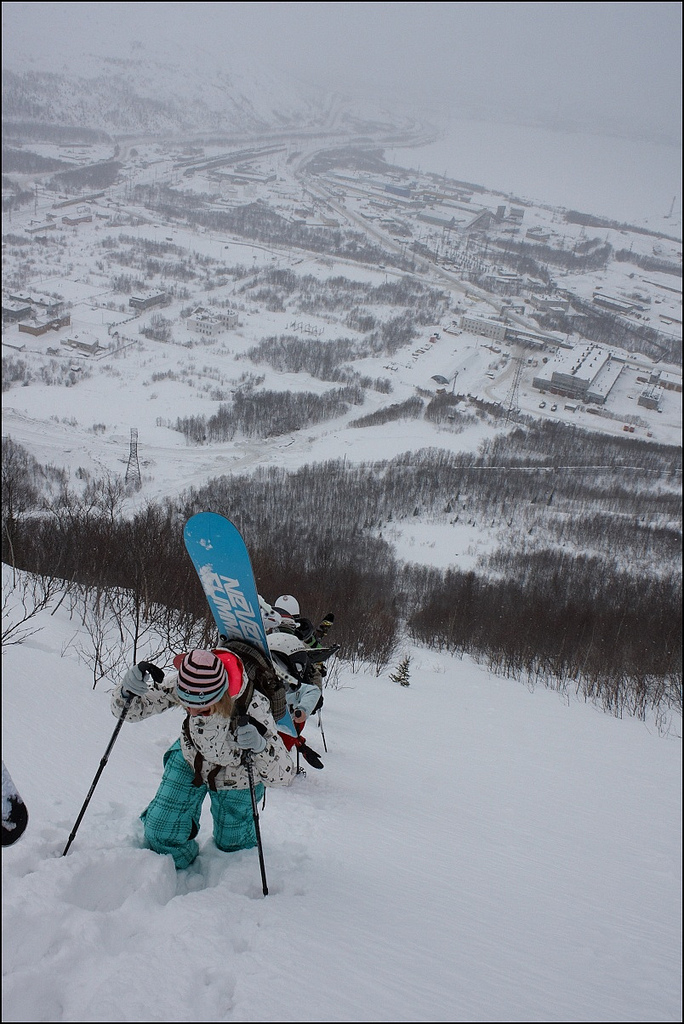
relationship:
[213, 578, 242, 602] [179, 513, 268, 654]
letter on snowboard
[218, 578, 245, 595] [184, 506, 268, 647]
letter on snowboard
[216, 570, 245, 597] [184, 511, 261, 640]
letter on snowboard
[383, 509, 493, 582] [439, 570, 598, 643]
clearing in middle of dead trees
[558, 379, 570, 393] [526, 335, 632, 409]
wall side building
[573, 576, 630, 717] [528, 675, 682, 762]
shrub on ground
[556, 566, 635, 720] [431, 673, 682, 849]
shrub on ground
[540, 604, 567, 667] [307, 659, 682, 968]
shrub in ground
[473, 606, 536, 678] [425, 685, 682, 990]
shrub in ground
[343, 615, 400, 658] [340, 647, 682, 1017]
shrub on ground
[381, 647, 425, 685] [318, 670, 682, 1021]
shrub in ground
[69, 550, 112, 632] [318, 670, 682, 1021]
shrub in ground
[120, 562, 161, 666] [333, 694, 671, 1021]
shrub in ground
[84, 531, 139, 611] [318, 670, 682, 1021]
shrub in ground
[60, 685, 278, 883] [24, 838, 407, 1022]
ski poles in snow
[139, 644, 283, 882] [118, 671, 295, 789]
woman wearing jacket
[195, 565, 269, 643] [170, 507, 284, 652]
lettering on snowboard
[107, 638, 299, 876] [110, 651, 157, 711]
woman wearing glove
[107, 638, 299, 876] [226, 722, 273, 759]
woman wearing glove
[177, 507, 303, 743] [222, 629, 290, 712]
snowboard in backpack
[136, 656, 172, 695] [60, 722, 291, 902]
strap in ski poles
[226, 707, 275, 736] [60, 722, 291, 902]
strap in ski poles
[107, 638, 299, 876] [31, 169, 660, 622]
woman on mountainside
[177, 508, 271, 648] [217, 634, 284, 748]
snowboard attached to back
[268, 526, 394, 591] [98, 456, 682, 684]
trees at bottom of ravine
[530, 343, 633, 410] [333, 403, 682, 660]
building in valley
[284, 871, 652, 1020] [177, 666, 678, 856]
snow covering hill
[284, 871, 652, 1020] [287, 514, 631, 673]
snow covering trees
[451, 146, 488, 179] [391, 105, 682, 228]
snow covering water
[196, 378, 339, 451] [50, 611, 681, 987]
forest patch below hill